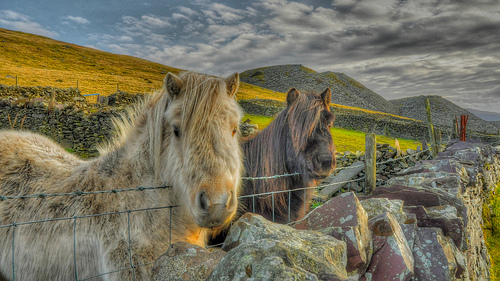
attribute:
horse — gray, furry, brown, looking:
[236, 84, 338, 217]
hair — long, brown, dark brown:
[243, 93, 321, 214]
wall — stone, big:
[150, 137, 493, 279]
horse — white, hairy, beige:
[1, 68, 245, 280]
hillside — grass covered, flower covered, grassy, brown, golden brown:
[1, 30, 499, 196]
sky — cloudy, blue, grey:
[1, 1, 499, 124]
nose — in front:
[312, 152, 334, 170]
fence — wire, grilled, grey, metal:
[5, 111, 483, 280]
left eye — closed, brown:
[229, 125, 240, 139]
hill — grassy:
[231, 63, 360, 113]